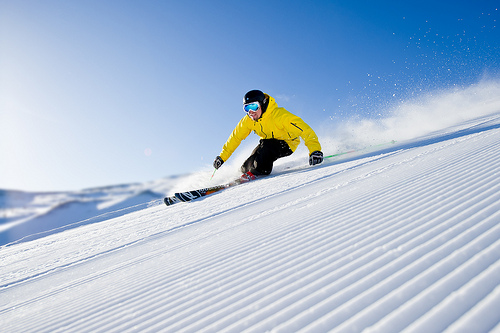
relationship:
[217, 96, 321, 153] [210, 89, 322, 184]
jacket on skier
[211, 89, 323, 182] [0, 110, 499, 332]
guy on ground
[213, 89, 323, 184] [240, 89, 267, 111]
guy wearing helmet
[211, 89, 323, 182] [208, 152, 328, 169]
guy wearing gloves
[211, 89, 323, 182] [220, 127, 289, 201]
guy wearing pants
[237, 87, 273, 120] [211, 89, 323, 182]
head of a guy